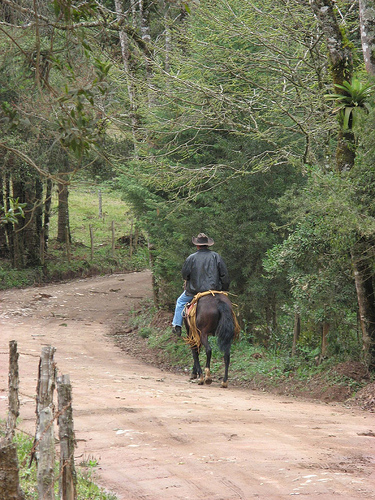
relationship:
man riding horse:
[171, 230, 237, 298] [188, 299, 239, 369]